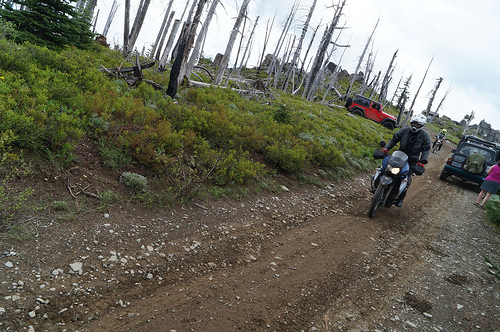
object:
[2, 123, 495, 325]
road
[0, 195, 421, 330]
rocks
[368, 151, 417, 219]
motorcycle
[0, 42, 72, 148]
bush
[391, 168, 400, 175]
headlight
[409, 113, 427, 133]
helmet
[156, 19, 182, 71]
trunk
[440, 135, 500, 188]
car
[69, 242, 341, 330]
dirt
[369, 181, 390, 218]
tire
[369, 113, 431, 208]
person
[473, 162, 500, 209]
person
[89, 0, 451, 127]
trees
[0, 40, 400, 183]
shrubs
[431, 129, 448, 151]
man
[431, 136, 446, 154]
motorcycle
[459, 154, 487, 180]
spare tire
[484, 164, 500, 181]
shirt